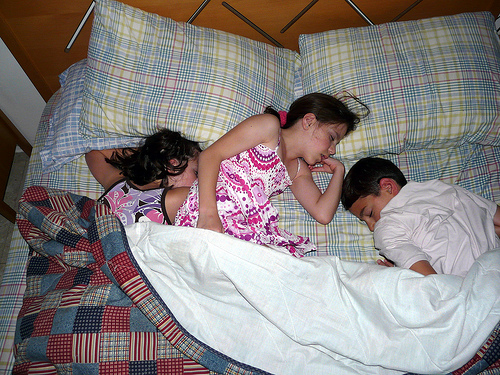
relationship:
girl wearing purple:
[85, 126, 203, 228] [97, 168, 176, 224]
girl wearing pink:
[174, 92, 362, 257] [247, 151, 273, 191]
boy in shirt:
[336, 154, 498, 278] [388, 184, 486, 267]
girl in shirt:
[73, 123, 193, 263] [99, 167, 171, 223]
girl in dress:
[228, 72, 356, 226] [171, 126, 319, 261]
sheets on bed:
[23, 56, 480, 266] [1, 1, 498, 371]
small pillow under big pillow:
[37, 54, 144, 174] [74, 4, 302, 151]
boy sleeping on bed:
[340, 154, 500, 278] [1, 1, 498, 371]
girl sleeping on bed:
[174, 92, 362, 257] [1, 1, 498, 371]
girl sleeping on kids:
[85, 126, 203, 228] [81, 86, 358, 250]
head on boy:
[339, 157, 407, 230] [336, 154, 498, 278]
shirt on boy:
[374, 176, 499, 274] [336, 154, 498, 278]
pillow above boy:
[298, 13, 498, 156] [336, 154, 498, 278]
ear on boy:
[376, 172, 403, 199] [341, 161, 447, 275]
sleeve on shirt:
[371, 214, 432, 267] [352, 166, 498, 288]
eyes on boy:
[364, 205, 375, 225] [342, 155, 494, 267]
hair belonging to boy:
[340, 155, 406, 209] [336, 154, 498, 278]